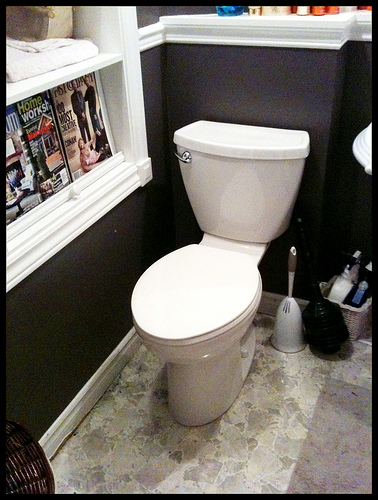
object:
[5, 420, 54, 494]
basket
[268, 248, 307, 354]
holder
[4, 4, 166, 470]
wall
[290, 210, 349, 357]
plunger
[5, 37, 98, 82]
towel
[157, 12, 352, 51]
ledge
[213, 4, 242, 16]
item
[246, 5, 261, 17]
item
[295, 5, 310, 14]
item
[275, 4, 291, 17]
item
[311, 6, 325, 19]
bottles things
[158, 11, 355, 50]
shelf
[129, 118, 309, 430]
toilet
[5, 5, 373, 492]
bathroom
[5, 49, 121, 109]
shelf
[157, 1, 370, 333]
wall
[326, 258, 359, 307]
cleaning supplies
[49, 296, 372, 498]
floor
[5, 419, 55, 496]
edge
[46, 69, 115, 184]
magazine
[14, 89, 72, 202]
magazine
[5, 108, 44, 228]
magazine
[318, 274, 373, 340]
basket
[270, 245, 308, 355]
brush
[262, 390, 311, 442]
design